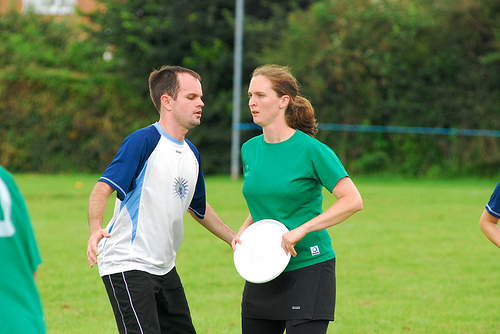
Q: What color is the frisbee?
A: White.